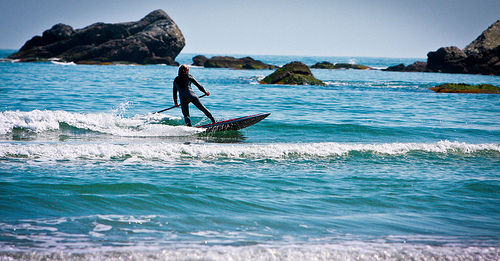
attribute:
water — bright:
[254, 82, 441, 254]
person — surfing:
[171, 64, 216, 126]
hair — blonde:
[174, 62, 192, 78]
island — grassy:
[283, 34, 437, 76]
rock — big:
[8, 7, 188, 72]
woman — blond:
[150, 66, 227, 109]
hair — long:
[173, 60, 194, 78]